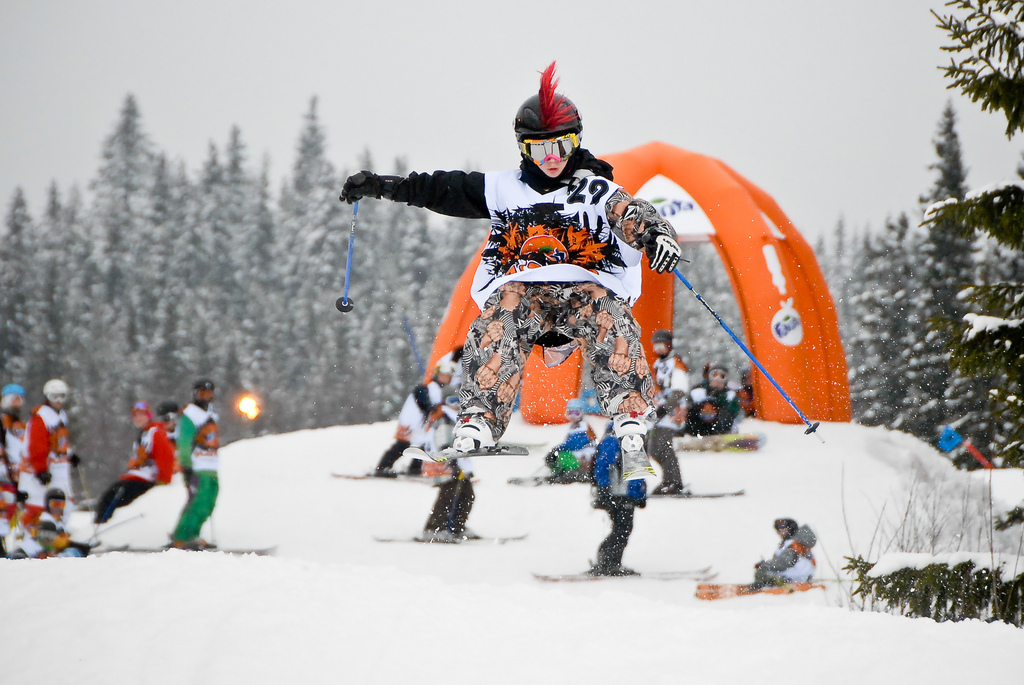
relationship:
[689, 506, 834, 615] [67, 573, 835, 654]
person sits in snow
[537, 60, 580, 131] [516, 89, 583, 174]
helmet on head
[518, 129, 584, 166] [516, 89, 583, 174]
goggles on head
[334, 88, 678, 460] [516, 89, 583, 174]
boy has head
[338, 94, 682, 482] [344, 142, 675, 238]
boy extending h arms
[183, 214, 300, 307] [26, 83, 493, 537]
snow on trees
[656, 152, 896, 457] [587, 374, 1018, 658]
dome on slope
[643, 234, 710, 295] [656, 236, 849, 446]
hand holding pole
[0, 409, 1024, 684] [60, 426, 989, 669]
ground surface on ground surface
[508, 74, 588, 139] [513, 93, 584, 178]
helmet on head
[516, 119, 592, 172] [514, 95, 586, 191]
goggles on skier's face